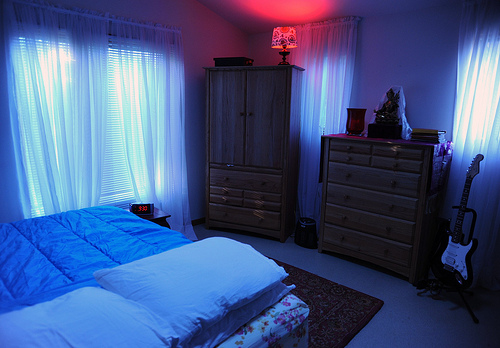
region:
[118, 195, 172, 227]
Digital clock on the table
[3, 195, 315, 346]
Bed has two pillows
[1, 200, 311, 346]
The bed is made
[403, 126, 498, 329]
Guitar is on a guitar stand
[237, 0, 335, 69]
Lamp emitting red light on ceiling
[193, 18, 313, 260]
Wardrobe doors are closed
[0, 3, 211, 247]
Light is coming from outside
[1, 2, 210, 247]
Blinds are under the drapes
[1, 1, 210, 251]
Drapes are see-through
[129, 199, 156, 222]
Clock says 9:30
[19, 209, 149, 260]
the comforter is blue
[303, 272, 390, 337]
the carpet is brown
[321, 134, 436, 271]
the cabinets are wooden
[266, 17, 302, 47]
the light is orange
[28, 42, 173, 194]
light is coming through the window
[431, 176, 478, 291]
guitar is on the stand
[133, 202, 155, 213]
the timer is on the stool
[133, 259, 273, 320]
the pillows are white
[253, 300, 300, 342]
flowers are on the sheet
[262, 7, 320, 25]
red light is on the ceiling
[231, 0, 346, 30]
red light on ceiling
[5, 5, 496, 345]
the room is illuminated blue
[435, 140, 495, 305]
an electric guitar on the ground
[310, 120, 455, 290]
a chest with drawers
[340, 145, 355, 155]
the handle of drawer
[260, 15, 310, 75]
a lamp with red light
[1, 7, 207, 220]
white curtains over window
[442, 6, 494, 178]
white curtains over window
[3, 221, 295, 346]
white pillows over the bed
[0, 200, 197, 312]
a blue comforter on bed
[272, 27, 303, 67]
a red lamp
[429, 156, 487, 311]
a guitar on a stand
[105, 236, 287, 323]
a white pillow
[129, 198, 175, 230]
an alarm clock on a table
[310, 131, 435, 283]
a dresser with drawers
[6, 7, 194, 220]
curtains on a window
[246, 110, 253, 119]
a knob on a cabinet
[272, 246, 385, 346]
oriental design throw rug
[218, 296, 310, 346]
a floral design sheet on a bed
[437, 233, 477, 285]
white on a guitar face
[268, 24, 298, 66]
lamp with patterned shade and red lightbulb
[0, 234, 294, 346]
pillows on bed with blue comforter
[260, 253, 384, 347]
red oriental floor rug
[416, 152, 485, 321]
black and white guitar on stand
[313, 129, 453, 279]
wooden dresser with books on top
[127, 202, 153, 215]
digital alarm clock with red display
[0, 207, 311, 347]
bed with blue comforter and floral sheets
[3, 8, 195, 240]
window with blinds and curtains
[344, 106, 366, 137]
red, upright glass vase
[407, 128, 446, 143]
stack of books with yellow book on top